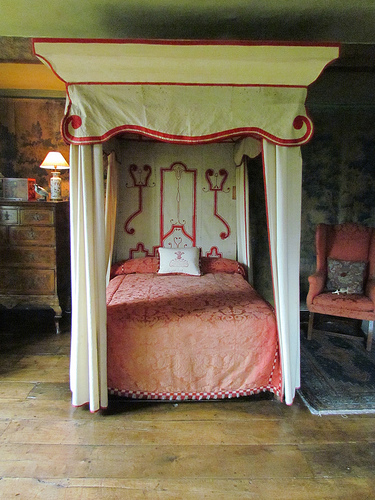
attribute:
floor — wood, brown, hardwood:
[0, 313, 373, 498]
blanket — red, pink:
[107, 256, 286, 403]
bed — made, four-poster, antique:
[40, 42, 340, 410]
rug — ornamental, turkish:
[287, 323, 374, 419]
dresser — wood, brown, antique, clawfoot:
[4, 205, 70, 334]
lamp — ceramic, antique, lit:
[40, 154, 66, 198]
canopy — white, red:
[30, 37, 343, 409]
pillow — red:
[201, 257, 248, 276]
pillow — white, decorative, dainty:
[153, 247, 203, 275]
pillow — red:
[112, 254, 157, 276]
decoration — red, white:
[120, 143, 247, 260]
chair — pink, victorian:
[302, 218, 374, 353]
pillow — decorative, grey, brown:
[325, 258, 369, 294]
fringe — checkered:
[105, 342, 284, 400]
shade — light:
[40, 154, 69, 172]